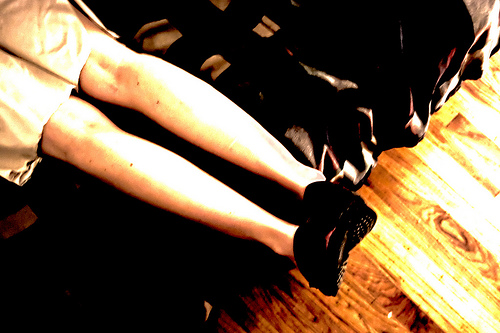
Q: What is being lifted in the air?
A: A pair of legs is lifted in the air.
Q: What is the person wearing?
A: The person is wearing black shoes.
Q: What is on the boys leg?
A: There is sun shining on the boy's right leg.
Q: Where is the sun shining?
A: The sun is shining on the boy's left leg.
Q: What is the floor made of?
A: Wood.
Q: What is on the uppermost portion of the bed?
A: Blankets.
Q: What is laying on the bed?
A: A person.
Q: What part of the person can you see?
A: Legs.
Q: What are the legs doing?
A: Resting.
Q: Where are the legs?
A: Next to each other.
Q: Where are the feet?
A: In the air.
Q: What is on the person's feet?
A: A pair of shoes on feet.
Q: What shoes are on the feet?
A: A pair of black shoes on feet.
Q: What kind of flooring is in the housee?
A: Naturally Stained Wooden Floor.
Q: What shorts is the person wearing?
A: Tan Above Knee Shorts.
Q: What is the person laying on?
A: Dark Plaid With White Comforter.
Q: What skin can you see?
A: Leg skin.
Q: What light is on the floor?
A: Sunlight.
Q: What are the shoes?
A: Black shoes.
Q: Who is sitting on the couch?
A: A person.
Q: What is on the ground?
A: Wood.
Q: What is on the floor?
A: Wood grain.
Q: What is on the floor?
A: A couch.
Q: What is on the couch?
A: A blanket.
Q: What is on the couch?
A: A person.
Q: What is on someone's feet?
A: Shoes.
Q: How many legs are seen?
A: Two.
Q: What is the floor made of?
A: Wood.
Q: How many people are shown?
A: One.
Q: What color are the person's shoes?
A: Black.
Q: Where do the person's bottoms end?
A: At knees.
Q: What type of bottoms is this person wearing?
A: Shorts.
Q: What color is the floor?
A: Brown.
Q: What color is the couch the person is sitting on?
A: Black.